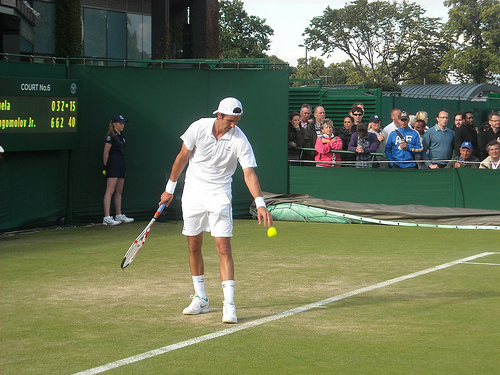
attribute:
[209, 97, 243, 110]
hat — white, backwards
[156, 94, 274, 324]
tennis player — playing, serving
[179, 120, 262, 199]
shirt — white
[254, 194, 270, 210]
band — white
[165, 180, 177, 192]
band — white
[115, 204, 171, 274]
tennis racket — blue, red, white, orange, black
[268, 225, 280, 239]
tennis ball — green, yellow, round, airborne, mid air, in air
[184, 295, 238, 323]
shoes — white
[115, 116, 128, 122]
hat — dark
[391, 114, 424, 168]
man — standing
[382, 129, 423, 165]
jacket — blue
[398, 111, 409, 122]
hat — blue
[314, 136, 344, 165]
coat — pink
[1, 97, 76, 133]
text — digital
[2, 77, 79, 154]
display — black, electronic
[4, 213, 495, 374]
tennis court — grass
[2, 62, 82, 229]
wall — green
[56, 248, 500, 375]
markings — white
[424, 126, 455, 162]
sweater — green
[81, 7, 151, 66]
doors — glass